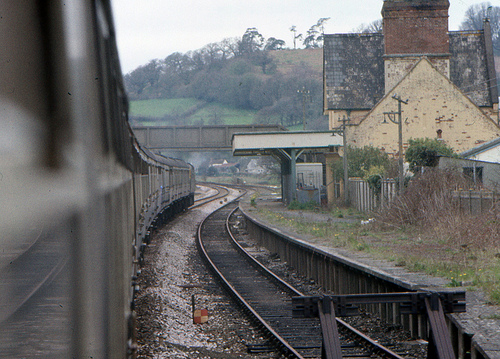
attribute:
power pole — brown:
[392, 92, 407, 194]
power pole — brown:
[336, 113, 348, 203]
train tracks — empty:
[196, 183, 330, 336]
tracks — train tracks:
[176, 112, 408, 340]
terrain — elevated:
[133, 93, 273, 165]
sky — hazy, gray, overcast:
[108, 1, 498, 79]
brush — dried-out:
[370, 163, 497, 265]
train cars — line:
[23, 2, 205, 357]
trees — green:
[196, 16, 363, 131]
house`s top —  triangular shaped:
[346, 55, 498, 154]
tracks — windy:
[128, 174, 483, 356]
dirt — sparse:
[345, 235, 390, 260]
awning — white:
[230, 131, 345, 155]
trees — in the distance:
[135, 38, 319, 118]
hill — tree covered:
[131, 49, 323, 124]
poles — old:
[392, 97, 414, 204]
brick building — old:
[314, 2, 499, 217]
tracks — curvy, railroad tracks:
[192, 247, 286, 299]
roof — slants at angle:
[322, 32, 493, 110]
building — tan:
[276, 25, 456, 207]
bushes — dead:
[390, 175, 485, 237]